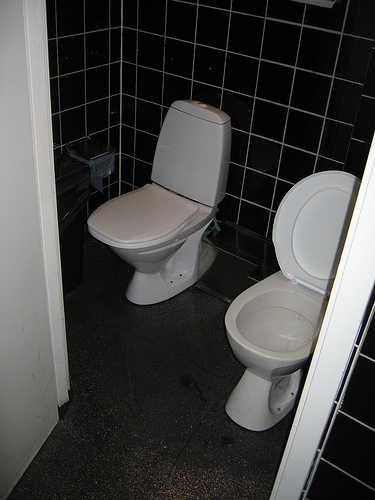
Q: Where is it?
A: This is at the bathroom.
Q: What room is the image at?
A: It is at the bathroom.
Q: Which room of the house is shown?
A: It is a bathroom.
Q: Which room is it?
A: It is a bathroom.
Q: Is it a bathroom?
A: Yes, it is a bathroom.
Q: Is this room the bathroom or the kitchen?
A: It is the bathroom.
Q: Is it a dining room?
A: No, it is a bathroom.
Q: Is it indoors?
A: Yes, it is indoors.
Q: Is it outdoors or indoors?
A: It is indoors.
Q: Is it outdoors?
A: No, it is indoors.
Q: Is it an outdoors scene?
A: No, it is indoors.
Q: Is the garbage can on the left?
A: Yes, the garbage can is on the left of the image.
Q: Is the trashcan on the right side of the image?
A: No, the trashcan is on the left of the image.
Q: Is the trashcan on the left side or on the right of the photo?
A: The trashcan is on the left of the image.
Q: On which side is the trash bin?
A: The trash bin is on the left of the image.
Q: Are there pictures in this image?
A: No, there are no pictures.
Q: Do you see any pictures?
A: No, there are no pictures.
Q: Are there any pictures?
A: No, there are no pictures.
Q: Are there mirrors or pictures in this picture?
A: No, there are no pictures or mirrors.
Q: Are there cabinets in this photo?
A: No, there are no cabinets.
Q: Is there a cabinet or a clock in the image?
A: No, there are no cabinets or clocks.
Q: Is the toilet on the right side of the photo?
A: Yes, the toilet is on the right of the image.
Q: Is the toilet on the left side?
A: No, the toilet is on the right of the image.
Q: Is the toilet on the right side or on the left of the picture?
A: The toilet is on the right of the image.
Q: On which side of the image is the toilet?
A: The toilet is on the right of the image.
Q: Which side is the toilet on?
A: The toilet is on the right of the image.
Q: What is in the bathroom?
A: The toilet is in the bathroom.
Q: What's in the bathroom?
A: The toilet is in the bathroom.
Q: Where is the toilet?
A: The toilet is in the bathroom.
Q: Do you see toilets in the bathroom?
A: Yes, there is a toilet in the bathroom.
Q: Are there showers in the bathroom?
A: No, there is a toilet in the bathroom.